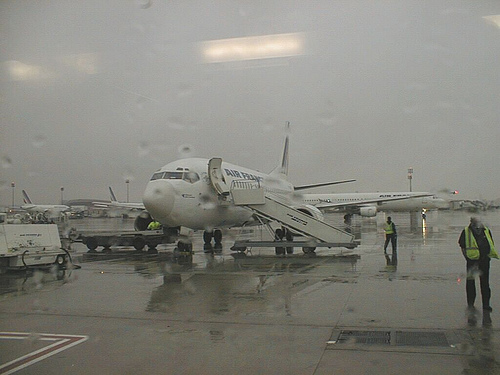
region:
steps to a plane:
[232, 181, 364, 255]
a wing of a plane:
[295, 183, 465, 203]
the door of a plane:
[206, 156, 234, 198]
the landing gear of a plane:
[201, 225, 223, 250]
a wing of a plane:
[61, 193, 141, 213]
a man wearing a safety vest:
[454, 213, 499, 299]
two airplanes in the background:
[15, 185, 152, 215]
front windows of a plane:
[143, 168, 205, 183]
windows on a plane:
[225, 161, 275, 181]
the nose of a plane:
[136, 176, 187, 222]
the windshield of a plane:
[144, 162, 200, 187]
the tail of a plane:
[263, 115, 358, 197]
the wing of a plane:
[270, 178, 446, 228]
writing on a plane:
[218, 164, 270, 185]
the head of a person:
[460, 208, 492, 238]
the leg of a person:
[455, 258, 481, 318]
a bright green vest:
[458, 220, 497, 266]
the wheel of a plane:
[197, 223, 234, 247]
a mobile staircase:
[240, 183, 369, 258]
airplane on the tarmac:
[128, 126, 430, 266]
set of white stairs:
[233, 182, 362, 251]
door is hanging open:
[207, 152, 232, 203]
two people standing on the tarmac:
[374, 211, 496, 317]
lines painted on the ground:
[8, 326, 89, 371]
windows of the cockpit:
[146, 166, 191, 183]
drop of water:
[176, 138, 196, 159]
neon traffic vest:
[460, 223, 499, 257]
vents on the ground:
[327, 309, 477, 356]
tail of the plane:
[266, 125, 313, 174]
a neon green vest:
[457, 222, 498, 269]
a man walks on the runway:
[383, 215, 404, 250]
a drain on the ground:
[331, 320, 458, 356]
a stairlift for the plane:
[235, 180, 356, 262]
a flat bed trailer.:
[67, 222, 159, 257]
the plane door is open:
[204, 149, 231, 201]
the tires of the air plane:
[197, 223, 298, 247]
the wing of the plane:
[302, 182, 457, 213]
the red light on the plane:
[451, 188, 460, 198]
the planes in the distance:
[17, 189, 147, 221]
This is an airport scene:
[16, 20, 491, 362]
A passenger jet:
[98, 118, 434, 285]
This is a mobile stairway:
[226, 172, 362, 269]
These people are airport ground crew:
[378, 212, 498, 311]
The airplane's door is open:
[204, 155, 240, 208]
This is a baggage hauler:
[66, 220, 171, 265]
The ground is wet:
[158, 262, 305, 349]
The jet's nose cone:
[136, 181, 191, 224]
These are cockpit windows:
[145, 166, 201, 188]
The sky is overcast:
[115, 60, 212, 162]